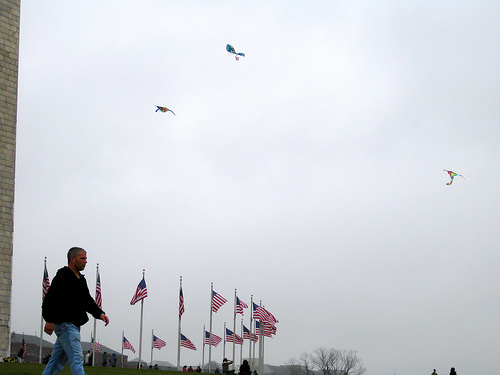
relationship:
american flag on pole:
[129, 279, 148, 306] [136, 299, 144, 370]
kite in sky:
[223, 42, 245, 62] [11, 24, 498, 374]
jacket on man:
[44, 236, 121, 371] [39, 236, 120, 334]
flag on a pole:
[39, 257, 52, 301] [37, 251, 51, 360]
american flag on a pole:
[129, 279, 148, 306] [141, 255, 191, 374]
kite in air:
[223, 42, 245, 62] [107, 49, 337, 228]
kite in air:
[119, 57, 212, 165] [136, 98, 383, 218]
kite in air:
[435, 164, 470, 192] [170, 124, 351, 297]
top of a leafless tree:
[281, 298, 401, 375] [288, 342, 355, 373]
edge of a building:
[12, 325, 37, 375] [0, 2, 17, 364]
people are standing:
[178, 352, 244, 372] [17, 218, 496, 375]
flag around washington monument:
[41, 266, 52, 301] [1, 94, 484, 374]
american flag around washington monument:
[211, 290, 229, 313] [22, 249, 473, 375]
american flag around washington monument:
[130, 276, 145, 304] [16, 332, 132, 367]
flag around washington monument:
[63, 296, 261, 375] [28, 171, 474, 375]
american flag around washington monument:
[119, 337, 138, 353] [16, 325, 136, 371]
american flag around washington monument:
[252, 302, 271, 320] [0, 2, 22, 359]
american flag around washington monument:
[210, 290, 227, 315] [0, 2, 22, 359]